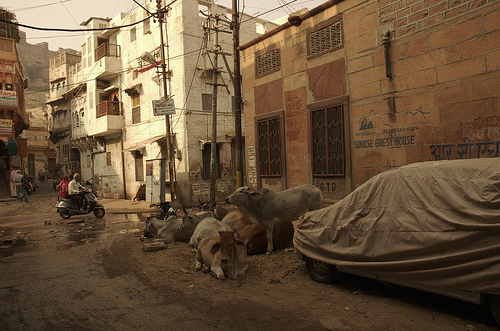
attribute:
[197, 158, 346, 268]
cow — white, side, laying, standing, herd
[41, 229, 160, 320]
road — dirt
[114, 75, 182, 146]
sign — white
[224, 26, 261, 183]
pole — tall, telephone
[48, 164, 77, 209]
shirt — red, white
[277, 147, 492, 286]
cover — white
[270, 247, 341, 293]
tire — showing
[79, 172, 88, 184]
man — riding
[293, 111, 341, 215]
fence — red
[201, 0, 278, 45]
line — power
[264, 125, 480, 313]
car — wrapped, flat, covered, over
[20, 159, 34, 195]
men — walking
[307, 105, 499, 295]
vehicle — parked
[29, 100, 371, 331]
street — wet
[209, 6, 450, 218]
building — apartment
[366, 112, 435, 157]
writing — blue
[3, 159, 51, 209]
people — walking, driving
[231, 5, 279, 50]
wire — electrical